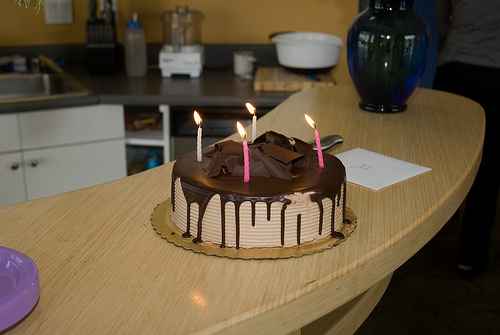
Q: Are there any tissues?
A: No, there are no tissues.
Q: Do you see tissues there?
A: No, there are no tissues.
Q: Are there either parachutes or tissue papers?
A: No, there are no tissue papers or parachutes.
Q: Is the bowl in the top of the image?
A: Yes, the bowl is in the top of the image.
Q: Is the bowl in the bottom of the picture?
A: No, the bowl is in the top of the image.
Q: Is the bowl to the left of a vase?
A: Yes, the bowl is to the left of a vase.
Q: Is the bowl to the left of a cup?
A: No, the bowl is to the left of a vase.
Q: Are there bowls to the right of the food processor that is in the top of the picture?
A: Yes, there is a bowl to the right of the food processor.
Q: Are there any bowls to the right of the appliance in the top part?
A: Yes, there is a bowl to the right of the food processor.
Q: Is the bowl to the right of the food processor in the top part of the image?
A: Yes, the bowl is to the right of the food processor.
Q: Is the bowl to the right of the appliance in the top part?
A: Yes, the bowl is to the right of the food processor.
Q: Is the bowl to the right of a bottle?
A: No, the bowl is to the right of the food processor.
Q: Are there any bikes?
A: No, there are no bikes.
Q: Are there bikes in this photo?
A: No, there are no bikes.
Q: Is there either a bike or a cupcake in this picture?
A: No, there are no bikes or cupcakes.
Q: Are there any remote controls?
A: No, there are no remote controls.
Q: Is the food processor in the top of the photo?
A: Yes, the food processor is in the top of the image.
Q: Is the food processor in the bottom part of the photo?
A: No, the food processor is in the top of the image.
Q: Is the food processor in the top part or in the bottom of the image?
A: The food processor is in the top of the image.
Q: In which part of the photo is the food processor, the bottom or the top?
A: The food processor is in the top of the image.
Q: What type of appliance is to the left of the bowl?
A: The appliance is a food processor.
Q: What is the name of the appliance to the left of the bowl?
A: The appliance is a food processor.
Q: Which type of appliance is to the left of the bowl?
A: The appliance is a food processor.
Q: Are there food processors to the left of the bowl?
A: Yes, there is a food processor to the left of the bowl.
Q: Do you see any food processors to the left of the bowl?
A: Yes, there is a food processor to the left of the bowl.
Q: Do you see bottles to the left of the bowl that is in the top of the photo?
A: No, there is a food processor to the left of the bowl.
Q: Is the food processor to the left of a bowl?
A: Yes, the food processor is to the left of a bowl.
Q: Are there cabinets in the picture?
A: Yes, there is a cabinet.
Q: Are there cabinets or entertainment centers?
A: Yes, there is a cabinet.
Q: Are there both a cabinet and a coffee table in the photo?
A: No, there is a cabinet but no coffee tables.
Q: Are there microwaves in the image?
A: No, there are no microwaves.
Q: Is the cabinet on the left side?
A: Yes, the cabinet is on the left of the image.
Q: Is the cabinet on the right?
A: No, the cabinet is on the left of the image.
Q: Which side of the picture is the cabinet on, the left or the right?
A: The cabinet is on the left of the image.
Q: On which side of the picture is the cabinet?
A: The cabinet is on the left of the image.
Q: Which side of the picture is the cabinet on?
A: The cabinet is on the left of the image.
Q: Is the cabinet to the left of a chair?
A: No, the cabinet is to the left of a candle.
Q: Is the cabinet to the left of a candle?
A: Yes, the cabinet is to the left of a candle.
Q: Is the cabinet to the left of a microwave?
A: No, the cabinet is to the left of a candle.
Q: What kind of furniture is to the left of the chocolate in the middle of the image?
A: The piece of furniture is a cabinet.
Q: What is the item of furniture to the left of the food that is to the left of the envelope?
A: The piece of furniture is a cabinet.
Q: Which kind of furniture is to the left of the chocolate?
A: The piece of furniture is a cabinet.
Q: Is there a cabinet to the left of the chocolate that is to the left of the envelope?
A: Yes, there is a cabinet to the left of the chocolate.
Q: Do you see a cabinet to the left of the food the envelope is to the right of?
A: Yes, there is a cabinet to the left of the chocolate.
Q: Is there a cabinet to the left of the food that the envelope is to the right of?
A: Yes, there is a cabinet to the left of the chocolate.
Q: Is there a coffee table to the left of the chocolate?
A: No, there is a cabinet to the left of the chocolate.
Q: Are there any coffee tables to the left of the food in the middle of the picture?
A: No, there is a cabinet to the left of the chocolate.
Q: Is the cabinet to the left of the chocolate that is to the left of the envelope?
A: Yes, the cabinet is to the left of the chocolate.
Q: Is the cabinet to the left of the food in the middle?
A: Yes, the cabinet is to the left of the chocolate.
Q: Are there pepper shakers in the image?
A: No, there are no pepper shakers.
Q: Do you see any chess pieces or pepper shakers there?
A: No, there are no pepper shakers or chess pieces.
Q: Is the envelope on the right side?
A: Yes, the envelope is on the right of the image.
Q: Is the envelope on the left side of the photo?
A: No, the envelope is on the right of the image.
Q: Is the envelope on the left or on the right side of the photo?
A: The envelope is on the right of the image.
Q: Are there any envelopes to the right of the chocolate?
A: Yes, there is an envelope to the right of the chocolate.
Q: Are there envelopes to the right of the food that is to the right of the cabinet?
A: Yes, there is an envelope to the right of the chocolate.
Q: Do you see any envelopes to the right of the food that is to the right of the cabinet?
A: Yes, there is an envelope to the right of the chocolate.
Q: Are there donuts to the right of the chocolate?
A: No, there is an envelope to the right of the chocolate.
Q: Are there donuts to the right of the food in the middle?
A: No, there is an envelope to the right of the chocolate.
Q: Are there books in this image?
A: No, there are no books.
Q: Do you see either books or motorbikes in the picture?
A: No, there are no books or motorbikes.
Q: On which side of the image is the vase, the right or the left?
A: The vase is on the right of the image.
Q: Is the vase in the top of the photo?
A: Yes, the vase is in the top of the image.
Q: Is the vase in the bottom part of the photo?
A: No, the vase is in the top of the image.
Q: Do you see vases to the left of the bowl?
A: No, the vase is to the right of the bowl.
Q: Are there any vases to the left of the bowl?
A: No, the vase is to the right of the bowl.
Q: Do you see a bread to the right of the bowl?
A: No, there is a vase to the right of the bowl.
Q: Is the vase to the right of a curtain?
A: No, the vase is to the right of the bowl.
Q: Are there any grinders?
A: No, there are no grinders.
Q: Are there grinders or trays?
A: No, there are no grinders or trays.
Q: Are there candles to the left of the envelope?
A: Yes, there is a candle to the left of the envelope.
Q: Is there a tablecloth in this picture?
A: No, there are no tablecloths.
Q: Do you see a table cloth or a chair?
A: No, there are no tablecloths or chairs.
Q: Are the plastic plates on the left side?
A: Yes, the plates are on the left of the image.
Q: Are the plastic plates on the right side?
A: No, the plates are on the left of the image.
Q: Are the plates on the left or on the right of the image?
A: The plates are on the left of the image.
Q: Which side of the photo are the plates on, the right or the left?
A: The plates are on the left of the image.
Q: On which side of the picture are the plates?
A: The plates are on the left of the image.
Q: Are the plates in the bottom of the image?
A: Yes, the plates are in the bottom of the image.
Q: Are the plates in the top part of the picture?
A: No, the plates are in the bottom of the image.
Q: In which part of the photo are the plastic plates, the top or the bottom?
A: The plates are in the bottom of the image.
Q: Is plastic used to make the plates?
A: Yes, the plates are made of plastic.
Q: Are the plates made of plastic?
A: Yes, the plates are made of plastic.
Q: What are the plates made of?
A: The plates are made of plastic.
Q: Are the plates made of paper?
A: No, the plates are made of plastic.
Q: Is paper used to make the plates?
A: No, the plates are made of plastic.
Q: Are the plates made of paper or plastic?
A: The plates are made of plastic.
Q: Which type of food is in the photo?
A: The food is chocolate.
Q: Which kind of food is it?
A: The food is chocolate.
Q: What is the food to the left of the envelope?
A: The food is chocolate.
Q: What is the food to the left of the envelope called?
A: The food is chocolate.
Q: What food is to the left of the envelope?
A: The food is chocolate.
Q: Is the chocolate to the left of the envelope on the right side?
A: Yes, the chocolate is to the left of the envelope.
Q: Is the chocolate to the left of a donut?
A: No, the chocolate is to the left of the envelope.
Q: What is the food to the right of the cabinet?
A: The food is chocolate.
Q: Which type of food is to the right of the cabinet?
A: The food is chocolate.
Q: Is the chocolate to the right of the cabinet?
A: Yes, the chocolate is to the right of the cabinet.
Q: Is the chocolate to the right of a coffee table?
A: No, the chocolate is to the right of the cabinet.